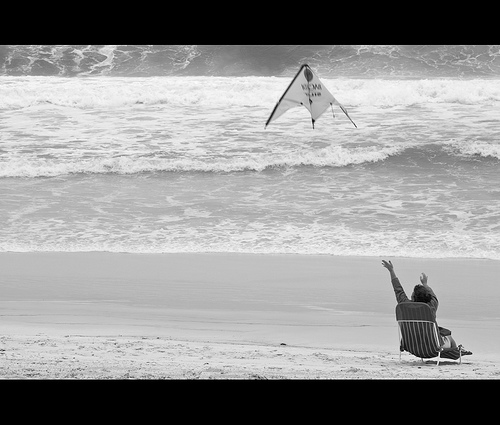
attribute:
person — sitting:
[398, 280, 435, 302]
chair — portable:
[391, 300, 473, 367]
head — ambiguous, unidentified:
[411, 285, 432, 303]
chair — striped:
[393, 293, 471, 372]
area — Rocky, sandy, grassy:
[8, 338, 496, 382]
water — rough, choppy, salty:
[12, 46, 242, 256]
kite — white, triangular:
[263, 64, 357, 132]